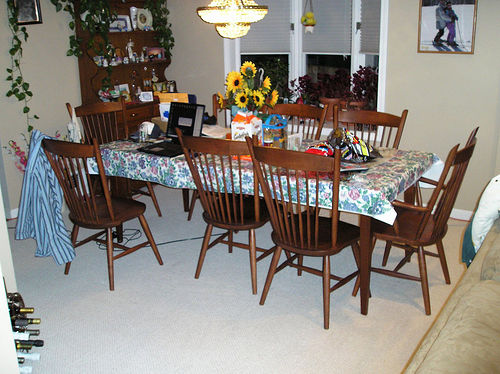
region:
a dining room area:
[18, 16, 471, 275]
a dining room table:
[57, 86, 447, 248]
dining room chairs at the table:
[44, 133, 342, 280]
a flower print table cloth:
[110, 146, 191, 188]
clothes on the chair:
[21, 136, 146, 287]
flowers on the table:
[197, 62, 285, 114]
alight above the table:
[193, 2, 300, 39]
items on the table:
[228, 113, 373, 180]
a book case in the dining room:
[73, 3, 179, 138]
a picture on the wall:
[410, 3, 479, 66]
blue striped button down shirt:
[16, 127, 84, 272]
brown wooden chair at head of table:
[347, 120, 497, 302]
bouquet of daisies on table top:
[221, 54, 282, 121]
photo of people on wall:
[408, 0, 480, 57]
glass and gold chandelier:
[182, 2, 278, 43]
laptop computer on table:
[130, 95, 210, 161]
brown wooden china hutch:
[63, 1, 200, 150]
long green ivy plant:
[4, 0, 193, 141]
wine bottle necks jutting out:
[6, 278, 51, 373]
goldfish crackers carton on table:
[225, 107, 267, 165]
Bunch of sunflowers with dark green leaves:
[221, 56, 283, 113]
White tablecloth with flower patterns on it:
[84, 132, 445, 224]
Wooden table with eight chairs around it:
[31, 91, 481, 331]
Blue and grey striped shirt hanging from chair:
[13, 125, 83, 267]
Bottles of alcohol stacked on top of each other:
[6, 288, 51, 372]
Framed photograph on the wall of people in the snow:
[414, 0, 480, 57]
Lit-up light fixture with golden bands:
[196, 0, 271, 41]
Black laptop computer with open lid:
[136, 98, 207, 159]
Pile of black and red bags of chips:
[299, 126, 384, 176]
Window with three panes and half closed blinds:
[225, 1, 388, 135]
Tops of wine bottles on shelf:
[4, 293, 44, 361]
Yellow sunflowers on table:
[216, 58, 276, 106]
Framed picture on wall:
[414, 0, 479, 55]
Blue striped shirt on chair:
[17, 130, 78, 266]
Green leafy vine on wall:
[9, 4, 38, 137]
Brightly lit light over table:
[199, 0, 267, 39]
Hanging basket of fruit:
[302, 5, 319, 29]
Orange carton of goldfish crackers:
[232, 111, 263, 162]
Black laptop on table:
[138, 100, 205, 157]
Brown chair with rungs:
[245, 138, 367, 329]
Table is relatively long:
[52, 68, 492, 312]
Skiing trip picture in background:
[423, 3, 470, 53]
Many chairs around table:
[58, 81, 482, 297]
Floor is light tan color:
[16, 241, 428, 368]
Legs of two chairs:
[200, 230, 373, 329]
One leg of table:
[353, 213, 380, 320]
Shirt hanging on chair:
[8, 122, 86, 281]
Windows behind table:
[238, 40, 377, 110]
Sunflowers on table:
[216, 61, 293, 118]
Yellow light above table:
[192, 5, 270, 42]